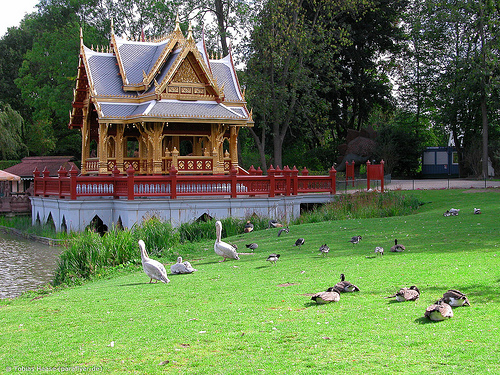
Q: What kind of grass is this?
A: This is dark green grass.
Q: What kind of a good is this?
A: This is a Canadian goose.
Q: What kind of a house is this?
A: This is a mobile home.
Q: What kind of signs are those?
A: Those are red signs.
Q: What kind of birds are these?
A: These are white birds.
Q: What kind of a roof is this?
A: This is a gray roof.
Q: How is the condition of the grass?
A: Lush and neatly trimmed.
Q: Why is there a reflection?
A: Light on water surface.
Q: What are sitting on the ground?
A: Birds.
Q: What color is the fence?
A: Red.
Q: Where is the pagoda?
A: Behind the fence.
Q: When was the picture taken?
A: Day time.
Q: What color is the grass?
A: Green.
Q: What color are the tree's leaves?
A: Green.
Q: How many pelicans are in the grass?
A: Three.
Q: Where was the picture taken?
A: At a park.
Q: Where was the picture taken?
A: In china.